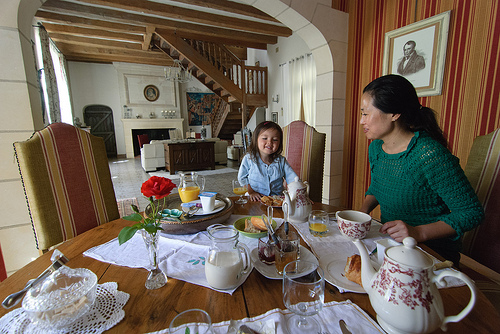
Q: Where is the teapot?
A: On the table.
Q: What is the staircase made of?
A: Wood.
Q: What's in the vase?
A: A single rose.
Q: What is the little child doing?
A: Eating breakfast.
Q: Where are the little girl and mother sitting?
A: At a dining table.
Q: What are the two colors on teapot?
A: Red and white.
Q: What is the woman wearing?
A: A green sweatshirt.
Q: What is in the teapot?
A: Tea.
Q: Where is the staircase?
A: In the background behind the little girl.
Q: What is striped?
A: The wall.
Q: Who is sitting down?
A: The woman.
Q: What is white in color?
A: The place mats.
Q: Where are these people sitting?
A: At a table.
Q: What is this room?
A: Kitchen.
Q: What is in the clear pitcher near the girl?
A: Orange juice.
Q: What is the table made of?
A: Wood.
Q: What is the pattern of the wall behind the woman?
A: Striped.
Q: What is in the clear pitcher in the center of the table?
A: Milk.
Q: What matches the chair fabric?
A: The wall behind the woman.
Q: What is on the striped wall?
A: A hanging picture.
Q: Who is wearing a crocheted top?
A: The woman.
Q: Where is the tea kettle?
A: On the table.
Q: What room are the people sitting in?
A: Dining Room.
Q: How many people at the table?
A: Two.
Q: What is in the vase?
A: Flower.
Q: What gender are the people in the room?
A: Female.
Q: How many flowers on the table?
A: One.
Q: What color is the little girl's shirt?
A: Blue.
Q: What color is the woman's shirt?
A: Green.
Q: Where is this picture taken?
A: In a dining room.